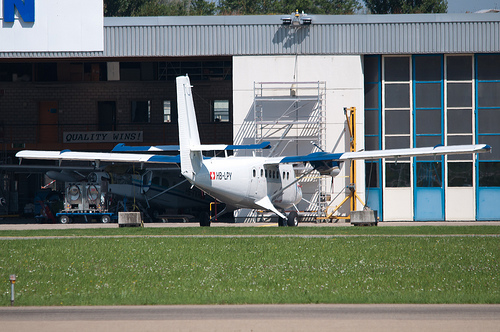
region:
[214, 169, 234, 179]
black letter print reading HB-LPY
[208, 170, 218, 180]
small red and white print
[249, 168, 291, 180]
row of small windows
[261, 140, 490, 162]
blue and white aircraft wing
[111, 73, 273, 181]
blue and white aircraft tail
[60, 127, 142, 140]
white banner with a bold text print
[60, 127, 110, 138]
bold print reading Quality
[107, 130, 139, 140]
bold print reading WINS!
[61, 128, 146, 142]
text on a white sign reading Quality Wins!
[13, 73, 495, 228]
white and blue jet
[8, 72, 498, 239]
this is an airplane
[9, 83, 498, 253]
the plane is white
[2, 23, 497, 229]
this is an airplane hangar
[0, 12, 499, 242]
this is a garage for planes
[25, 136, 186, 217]
there is a plane inside the building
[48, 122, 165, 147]
there is a white sign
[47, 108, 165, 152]
the sign says "QUALITY WINS!"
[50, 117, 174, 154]
a white sign inside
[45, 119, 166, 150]
there is a banner inside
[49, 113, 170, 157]
the banner says "quality wins!"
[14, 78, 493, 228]
Blue and white airplane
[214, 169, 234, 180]
Black letters on white plane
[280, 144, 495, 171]
Blue and white airplane wing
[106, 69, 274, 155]
Blue and white airplane tail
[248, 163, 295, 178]
Windows on an airplane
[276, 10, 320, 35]
Gray lights on front of building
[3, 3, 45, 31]
Blue letter on a white sign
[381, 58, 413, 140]
Tall white painted windowss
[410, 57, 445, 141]
Tall blue windows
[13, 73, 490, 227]
small blue and white airplane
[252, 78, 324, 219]
scaffolding on the side of a building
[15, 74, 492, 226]
airplane is a small passenger plane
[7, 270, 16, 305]
small light is in the grass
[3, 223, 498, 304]
grassy field at the airport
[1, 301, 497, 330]
paved runway at the airport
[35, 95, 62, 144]
orange door leading into building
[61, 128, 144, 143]
sign hanging up at the airport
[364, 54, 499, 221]
blue and white striped siding with several windows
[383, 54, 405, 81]
Small window on a building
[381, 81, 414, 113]
Small window on a building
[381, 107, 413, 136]
Small window on a building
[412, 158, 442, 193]
Small window on a building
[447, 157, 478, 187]
Small window on a building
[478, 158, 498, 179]
Small window on a building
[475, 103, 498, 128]
Small window on a building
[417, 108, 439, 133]
Small window on a building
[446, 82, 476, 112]
Small window on a building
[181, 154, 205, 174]
the paint is white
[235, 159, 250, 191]
the paint is white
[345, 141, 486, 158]
the paint is white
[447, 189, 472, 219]
the paint is white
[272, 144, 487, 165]
wing of a plane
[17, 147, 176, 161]
wing of a plane